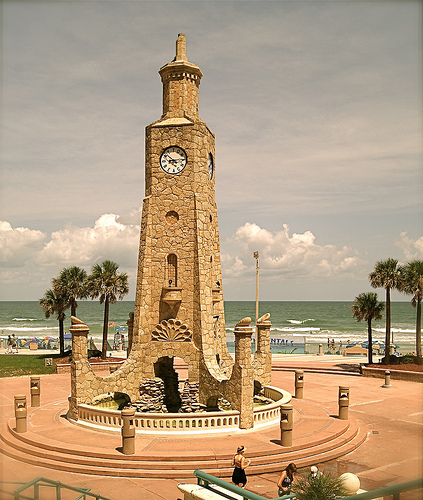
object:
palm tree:
[51, 264, 87, 359]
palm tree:
[82, 258, 129, 359]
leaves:
[61, 269, 80, 285]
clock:
[158, 146, 187, 179]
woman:
[276, 461, 296, 496]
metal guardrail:
[191, 469, 268, 500]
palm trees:
[347, 290, 385, 365]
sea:
[1, 300, 421, 339]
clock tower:
[64, 32, 274, 433]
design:
[149, 316, 194, 341]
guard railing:
[0, 475, 108, 499]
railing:
[0, 468, 103, 498]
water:
[0, 301, 422, 343]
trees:
[392, 254, 422, 357]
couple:
[5, 333, 18, 353]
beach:
[1, 333, 421, 361]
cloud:
[0, 207, 422, 299]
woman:
[231, 443, 250, 491]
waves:
[0, 316, 422, 347]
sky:
[0, 1, 421, 302]